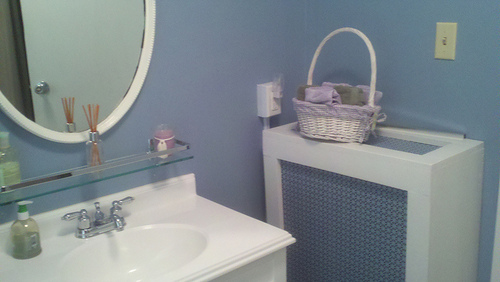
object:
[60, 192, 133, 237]
faucet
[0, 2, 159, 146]
frame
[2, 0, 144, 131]
mirror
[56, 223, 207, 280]
sink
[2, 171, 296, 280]
counter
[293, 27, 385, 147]
basket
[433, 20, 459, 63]
switch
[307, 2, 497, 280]
wall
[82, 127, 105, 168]
bottle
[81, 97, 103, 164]
incense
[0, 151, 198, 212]
shelf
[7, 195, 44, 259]
soap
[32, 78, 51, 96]
knob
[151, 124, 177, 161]
candle